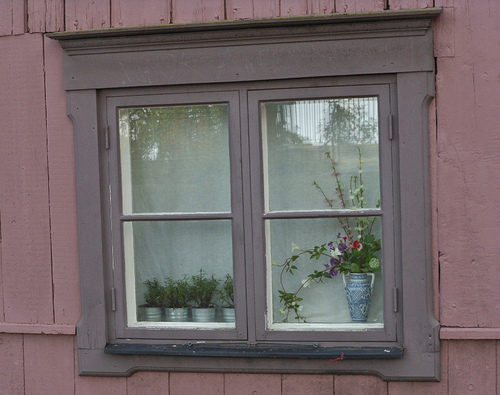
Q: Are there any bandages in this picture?
A: No, there are no bandages.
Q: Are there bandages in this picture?
A: No, there are no bandages.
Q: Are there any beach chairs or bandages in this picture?
A: No, there are no bandages or beach chairs.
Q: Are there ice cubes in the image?
A: No, there are no ice cubes.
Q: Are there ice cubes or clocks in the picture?
A: No, there are no ice cubes or clocks.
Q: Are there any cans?
A: Yes, there is a can.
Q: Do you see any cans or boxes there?
A: Yes, there is a can.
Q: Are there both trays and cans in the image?
A: No, there is a can but no trays.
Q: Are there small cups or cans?
A: Yes, there is a small can.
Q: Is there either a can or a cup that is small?
A: Yes, the can is small.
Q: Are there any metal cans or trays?
A: Yes, there is a metal can.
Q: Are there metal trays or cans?
A: Yes, there is a metal can.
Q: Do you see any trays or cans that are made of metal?
A: Yes, the can is made of metal.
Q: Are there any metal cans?
A: Yes, there is a metal can.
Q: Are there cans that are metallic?
A: Yes, there is a can that is metallic.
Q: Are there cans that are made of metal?
A: Yes, there is a can that is made of metal.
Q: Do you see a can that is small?
A: Yes, there is a small can.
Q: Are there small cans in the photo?
A: Yes, there is a small can.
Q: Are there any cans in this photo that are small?
A: Yes, there is a can that is small.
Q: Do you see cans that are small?
A: Yes, there is a can that is small.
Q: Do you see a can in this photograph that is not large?
A: Yes, there is a small can.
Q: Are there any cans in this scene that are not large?
A: Yes, there is a small can.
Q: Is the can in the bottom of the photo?
A: Yes, the can is in the bottom of the image.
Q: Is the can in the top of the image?
A: No, the can is in the bottom of the image.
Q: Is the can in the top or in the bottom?
A: The can is in the bottom of the image.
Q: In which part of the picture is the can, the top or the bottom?
A: The can is in the bottom of the image.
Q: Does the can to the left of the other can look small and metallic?
A: Yes, the can is small and metallic.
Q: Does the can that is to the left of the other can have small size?
A: Yes, the can is small.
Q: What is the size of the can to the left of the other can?
A: The can is small.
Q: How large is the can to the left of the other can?
A: The can is small.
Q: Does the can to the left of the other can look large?
A: No, the can is small.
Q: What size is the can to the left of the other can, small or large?
A: The can is small.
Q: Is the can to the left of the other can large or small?
A: The can is small.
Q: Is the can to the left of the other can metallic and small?
A: Yes, the can is metallic and small.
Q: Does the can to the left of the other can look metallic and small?
A: Yes, the can is metallic and small.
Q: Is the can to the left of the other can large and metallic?
A: No, the can is metallic but small.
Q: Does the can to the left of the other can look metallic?
A: Yes, the can is metallic.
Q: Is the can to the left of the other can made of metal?
A: Yes, the can is made of metal.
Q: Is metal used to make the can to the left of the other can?
A: Yes, the can is made of metal.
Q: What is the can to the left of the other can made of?
A: The can is made of metal.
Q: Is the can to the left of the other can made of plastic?
A: No, the can is made of metal.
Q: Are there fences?
A: No, there are no fences.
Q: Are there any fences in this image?
A: No, there are no fences.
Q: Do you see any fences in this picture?
A: No, there are no fences.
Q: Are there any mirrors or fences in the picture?
A: No, there are no fences or mirrors.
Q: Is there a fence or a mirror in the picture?
A: No, there are no fences or mirrors.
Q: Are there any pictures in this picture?
A: No, there are no pictures.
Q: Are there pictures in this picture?
A: No, there are no pictures.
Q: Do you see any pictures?
A: No, there are no pictures.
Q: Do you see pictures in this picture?
A: No, there are no pictures.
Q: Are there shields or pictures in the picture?
A: No, there are no pictures or shields.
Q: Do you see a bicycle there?
A: No, there are no bicycles.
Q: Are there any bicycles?
A: No, there are no bicycles.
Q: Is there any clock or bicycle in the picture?
A: No, there are no bicycles or clocks.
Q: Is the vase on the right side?
A: Yes, the vase is on the right of the image.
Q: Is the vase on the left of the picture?
A: No, the vase is on the right of the image.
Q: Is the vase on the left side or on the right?
A: The vase is on the right of the image.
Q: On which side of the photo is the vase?
A: The vase is on the right of the image.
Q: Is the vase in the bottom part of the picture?
A: Yes, the vase is in the bottom of the image.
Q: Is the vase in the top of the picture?
A: No, the vase is in the bottom of the image.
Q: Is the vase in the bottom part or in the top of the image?
A: The vase is in the bottom of the image.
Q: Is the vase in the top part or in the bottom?
A: The vase is in the bottom of the image.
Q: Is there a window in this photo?
A: Yes, there is a window.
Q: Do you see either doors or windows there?
A: Yes, there is a window.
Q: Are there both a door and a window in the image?
A: No, there is a window but no doors.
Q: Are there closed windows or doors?
A: Yes, there is a closed window.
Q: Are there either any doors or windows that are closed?
A: Yes, the window is closed.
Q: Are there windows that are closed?
A: Yes, there is a closed window.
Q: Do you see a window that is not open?
A: Yes, there is an closed window.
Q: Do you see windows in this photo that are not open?
A: Yes, there is an closed window.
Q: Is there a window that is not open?
A: Yes, there is an closed window.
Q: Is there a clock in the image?
A: No, there are no clocks.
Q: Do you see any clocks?
A: No, there are no clocks.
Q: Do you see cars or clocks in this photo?
A: No, there are no clocks or cars.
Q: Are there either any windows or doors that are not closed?
A: No, there is a window but it is closed.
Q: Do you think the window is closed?
A: Yes, the window is closed.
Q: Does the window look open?
A: No, the window is closed.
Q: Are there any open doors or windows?
A: No, there is a window but it is closed.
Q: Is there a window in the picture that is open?
A: No, there is a window but it is closed.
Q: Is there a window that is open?
A: No, there is a window but it is closed.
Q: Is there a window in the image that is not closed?
A: No, there is a window but it is closed.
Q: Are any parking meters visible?
A: No, there are no parking meters.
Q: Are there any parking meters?
A: No, there are no parking meters.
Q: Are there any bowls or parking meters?
A: No, there are no parking meters or bowls.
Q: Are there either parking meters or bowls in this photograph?
A: No, there are no parking meters or bowls.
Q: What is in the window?
A: The plants are in the window.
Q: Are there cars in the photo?
A: No, there are no cars.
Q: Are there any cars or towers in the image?
A: No, there are no cars or towers.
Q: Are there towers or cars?
A: No, there are no cars or towers.